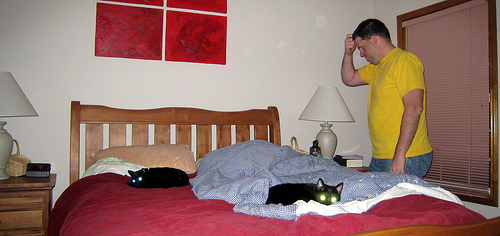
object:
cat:
[265, 178, 344, 206]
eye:
[320, 195, 325, 201]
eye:
[331, 197, 336, 202]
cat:
[126, 167, 190, 189]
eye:
[139, 177, 143, 181]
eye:
[132, 179, 136, 183]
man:
[341, 19, 434, 180]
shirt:
[358, 46, 434, 159]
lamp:
[0, 71, 38, 180]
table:
[0, 174, 56, 236]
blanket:
[46, 173, 488, 236]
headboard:
[69, 101, 281, 185]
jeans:
[368, 150, 434, 180]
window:
[396, 0, 499, 208]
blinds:
[401, 0, 492, 201]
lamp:
[297, 86, 355, 160]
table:
[349, 166, 369, 173]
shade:
[0, 72, 39, 117]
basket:
[4, 139, 31, 177]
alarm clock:
[26, 163, 51, 178]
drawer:
[0, 210, 43, 230]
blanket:
[190, 139, 464, 221]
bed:
[47, 101, 499, 236]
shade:
[298, 86, 356, 123]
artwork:
[95, 0, 227, 65]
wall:
[0, 0, 396, 210]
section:
[94, 2, 164, 60]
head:
[351, 19, 394, 65]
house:
[0, 0, 498, 234]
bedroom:
[1, 0, 498, 236]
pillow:
[92, 144, 197, 174]